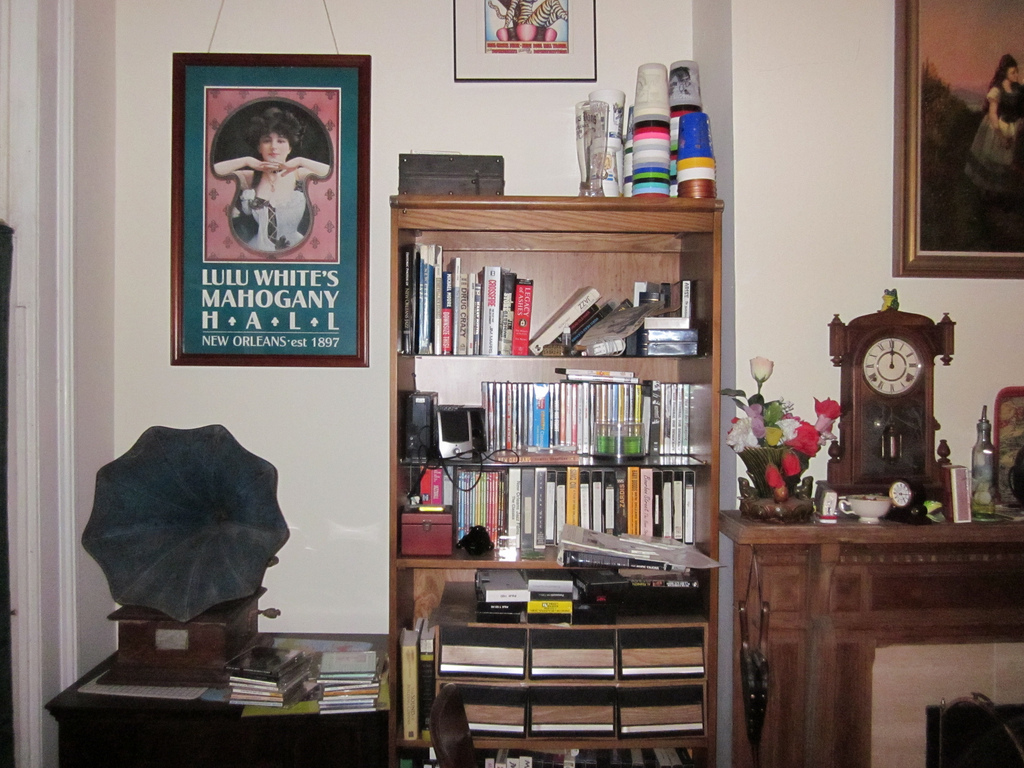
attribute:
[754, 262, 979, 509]
clock — wooden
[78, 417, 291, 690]
phonograph — old, crank-style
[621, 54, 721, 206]
cups — colorful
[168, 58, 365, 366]
antique art — hanging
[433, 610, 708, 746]
cd cases — old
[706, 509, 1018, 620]
mantle — wooden